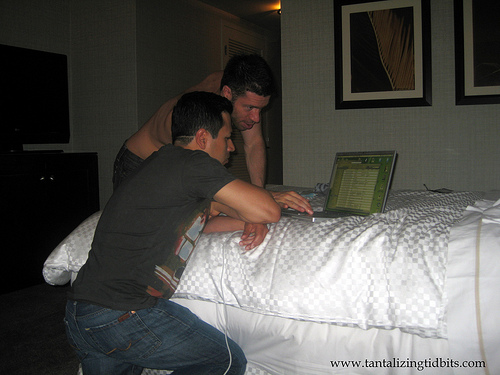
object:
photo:
[4, 2, 500, 375]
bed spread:
[238, 196, 448, 339]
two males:
[62, 47, 318, 373]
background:
[3, 5, 284, 373]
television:
[2, 44, 81, 150]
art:
[334, 0, 433, 113]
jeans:
[54, 285, 248, 374]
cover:
[177, 213, 466, 343]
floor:
[0, 285, 498, 371]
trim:
[464, 217, 499, 375]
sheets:
[43, 193, 499, 372]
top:
[232, 15, 285, 58]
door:
[244, 15, 287, 204]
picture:
[451, 6, 499, 107]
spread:
[35, 185, 496, 372]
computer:
[281, 149, 400, 226]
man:
[110, 52, 315, 218]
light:
[258, 0, 280, 17]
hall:
[226, 5, 284, 186]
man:
[61, 84, 284, 374]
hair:
[223, 54, 278, 100]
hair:
[168, 91, 235, 130]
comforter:
[285, 208, 419, 335]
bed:
[176, 190, 496, 374]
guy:
[108, 55, 315, 218]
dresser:
[1, 133, 150, 363]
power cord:
[201, 230, 248, 371]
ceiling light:
[250, 0, 280, 25]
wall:
[276, 8, 497, 192]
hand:
[261, 188, 316, 217]